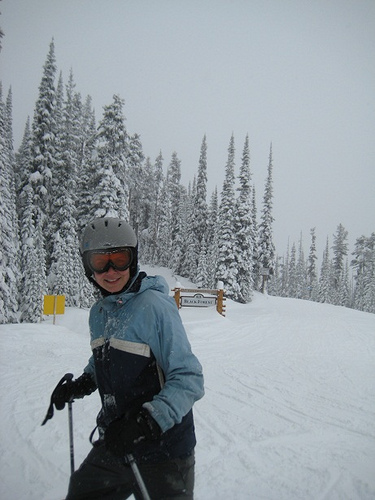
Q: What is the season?
A: Winter.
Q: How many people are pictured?
A: One.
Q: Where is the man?
A: On the mountain.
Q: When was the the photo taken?
A: Morning.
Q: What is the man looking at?
A: The camera.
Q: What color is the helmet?
A: Gray.